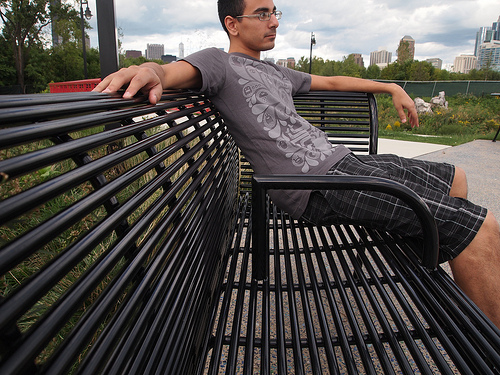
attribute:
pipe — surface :
[4, 81, 125, 127]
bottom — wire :
[224, 211, 441, 365]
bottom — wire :
[211, 184, 456, 369]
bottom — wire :
[238, 200, 439, 370]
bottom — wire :
[231, 190, 444, 373]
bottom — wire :
[231, 203, 453, 372]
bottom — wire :
[220, 200, 465, 366]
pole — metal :
[87, 2, 125, 169]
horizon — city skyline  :
[4, 22, 482, 72]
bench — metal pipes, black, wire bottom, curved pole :
[0, 84, 498, 372]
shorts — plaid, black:
[310, 132, 493, 275]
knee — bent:
[450, 164, 473, 200]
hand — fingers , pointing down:
[90, 60, 170, 106]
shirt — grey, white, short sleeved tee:
[178, 39, 353, 209]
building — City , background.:
[398, 33, 419, 59]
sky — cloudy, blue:
[120, 2, 200, 39]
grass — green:
[438, 121, 457, 133]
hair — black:
[216, 1, 252, 35]